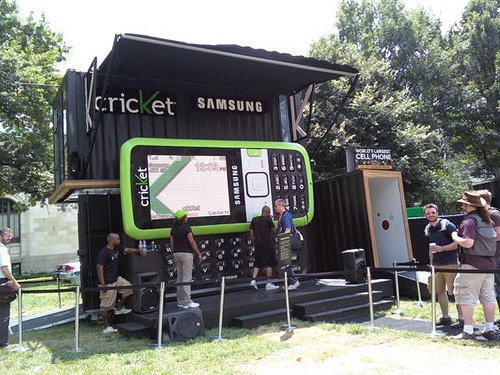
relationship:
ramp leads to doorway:
[381, 262, 447, 301] [360, 166, 413, 271]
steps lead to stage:
[291, 288, 393, 324] [118, 275, 385, 327]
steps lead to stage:
[233, 307, 293, 327] [118, 275, 385, 327]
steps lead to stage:
[115, 319, 148, 339] [118, 275, 385, 327]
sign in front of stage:
[122, 133, 325, 241] [118, 275, 385, 327]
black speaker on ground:
[112, 78, 348, 279] [18, 277, 498, 373]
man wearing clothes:
[246, 199, 282, 291] [248, 215, 278, 267]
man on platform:
[246, 199, 282, 291] [130, 275, 400, 311]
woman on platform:
[162, 206, 213, 310] [138, 269, 393, 331]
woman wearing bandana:
[162, 206, 213, 310] [171, 207, 186, 221]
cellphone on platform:
[113, 131, 318, 230] [121, 257, 392, 309]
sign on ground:
[90, 88, 175, 119] [18, 277, 498, 373]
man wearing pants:
[93, 228, 132, 335] [98, 274, 132, 309]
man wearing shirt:
[93, 228, 132, 335] [93, 245, 133, 287]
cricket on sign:
[92, 81, 181, 121] [75, 84, 185, 122]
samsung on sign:
[193, 93, 263, 114] [188, 93, 274, 115]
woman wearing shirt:
[168, 209, 204, 309] [168, 219, 195, 254]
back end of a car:
[57, 262, 73, 278] [54, 254, 82, 291]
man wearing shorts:
[418, 203, 456, 335] [421, 258, 456, 294]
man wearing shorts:
[448, 182, 498, 341] [450, 262, 499, 308]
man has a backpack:
[453, 190, 498, 344] [468, 209, 499, 259]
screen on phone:
[143, 153, 234, 219] [119, 136, 316, 240]